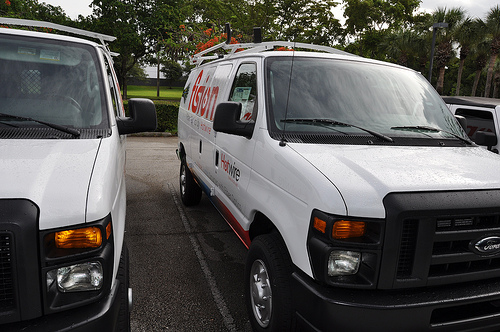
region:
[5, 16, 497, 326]
white trucks are parked side by side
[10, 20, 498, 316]
a shower has passed by the trucks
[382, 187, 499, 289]
the grill of the truck is black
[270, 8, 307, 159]
the truck has an antenna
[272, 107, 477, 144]
black windshield wipers are on the truck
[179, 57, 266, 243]
the truck has writing on the side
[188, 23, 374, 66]
a rack is on the roof of the truck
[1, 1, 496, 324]
the trucks are in a parking lot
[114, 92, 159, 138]
the rear side mirror is black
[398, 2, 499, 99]
palm trees are in back of the parking lot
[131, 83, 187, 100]
Green grass in the back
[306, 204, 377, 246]
orange light above headlight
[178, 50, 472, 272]
A white, black and red van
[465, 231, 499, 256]
the "Ford" emblem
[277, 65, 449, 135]
Windshield reflecting light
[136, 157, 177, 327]
parking lot blacktop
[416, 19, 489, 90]
palm trees swaying in the breeze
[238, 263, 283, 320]
a silver hubcap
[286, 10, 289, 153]
vans radio antenna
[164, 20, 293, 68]
red flowers in the tree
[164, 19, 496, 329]
vehicle parked in a lot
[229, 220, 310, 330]
front wheel on a vehicle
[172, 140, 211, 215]
rear wheel on a vehicle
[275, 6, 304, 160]
antenna on a vehicle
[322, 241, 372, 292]
front headlight on a vehicle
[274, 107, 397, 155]
windshield wiper on a vehicle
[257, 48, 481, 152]
front windshield on a vehicle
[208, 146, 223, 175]
door handle on a vehicle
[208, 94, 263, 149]
side rear view mirror on a vehicle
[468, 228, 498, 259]
manufacturers logo on a vehicle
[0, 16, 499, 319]
white trucks are parked in a lot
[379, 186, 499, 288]
the grill of the truck is flat black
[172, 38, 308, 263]
red lettering is on the side of the truck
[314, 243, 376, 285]
the headlight of the truck is off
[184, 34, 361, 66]
a rack is on top of the truck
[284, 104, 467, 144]
the front window has windshield wipers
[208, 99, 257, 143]
the rear view mirrors are black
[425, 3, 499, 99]
the palm trees are in the background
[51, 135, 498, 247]
a slight rain shower wet the trucks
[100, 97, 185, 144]
green hedges are behind the truck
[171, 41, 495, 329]
a large white van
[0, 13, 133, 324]
a large white van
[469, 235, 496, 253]
a Ford corporate logo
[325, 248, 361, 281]
a vehicle front headlight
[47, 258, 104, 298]
a vehicle front headlight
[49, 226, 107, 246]
a vehicle turn signal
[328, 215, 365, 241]
a vehicle turn signal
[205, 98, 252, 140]
a vehicle rear view mirror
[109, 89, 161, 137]
a vehicle rear view mirror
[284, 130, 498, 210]
a white van hood